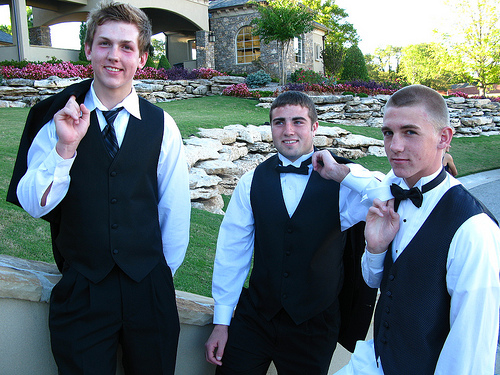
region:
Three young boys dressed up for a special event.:
[8, 1, 488, 357]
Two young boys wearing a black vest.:
[205, 81, 490, 371]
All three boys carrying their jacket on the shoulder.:
[10, 7, 477, 354]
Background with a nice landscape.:
[3, 5, 495, 320]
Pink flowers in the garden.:
[2, 57, 90, 77]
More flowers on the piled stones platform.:
[316, 77, 376, 122]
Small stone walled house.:
[207, 1, 327, 87]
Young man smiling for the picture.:
[85, 11, 154, 86]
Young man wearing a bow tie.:
[386, 170, 447, 208]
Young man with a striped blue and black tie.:
[93, 99, 125, 151]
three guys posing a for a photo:
[26, 7, 483, 362]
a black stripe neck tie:
[102, 113, 119, 150]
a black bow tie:
[271, 154, 311, 179]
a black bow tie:
[381, 177, 423, 205]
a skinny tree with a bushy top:
[261, 0, 303, 78]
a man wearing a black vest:
[25, 11, 192, 359]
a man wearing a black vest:
[222, 62, 354, 371]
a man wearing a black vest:
[376, 87, 460, 372]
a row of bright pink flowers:
[10, 59, 167, 79]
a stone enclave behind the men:
[187, 127, 360, 184]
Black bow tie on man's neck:
[388, 166, 450, 208]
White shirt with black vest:
[361, 168, 498, 374]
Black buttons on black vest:
[379, 268, 394, 349]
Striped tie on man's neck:
[96, 106, 125, 156]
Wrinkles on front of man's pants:
[51, 278, 123, 359]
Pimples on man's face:
[406, 149, 424, 167]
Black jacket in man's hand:
[4, 78, 95, 275]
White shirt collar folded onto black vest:
[78, 80, 140, 121]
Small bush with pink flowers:
[219, 82, 245, 96]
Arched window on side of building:
[233, 23, 263, 66]